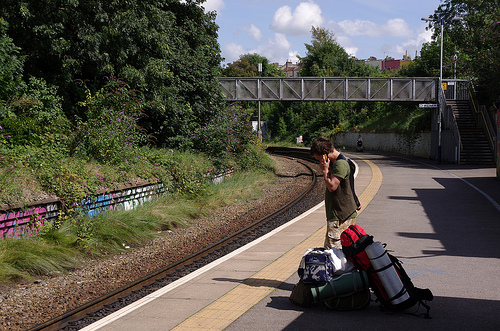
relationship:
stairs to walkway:
[429, 69, 496, 176] [420, 157, 487, 322]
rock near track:
[110, 224, 161, 266] [233, 183, 307, 244]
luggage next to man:
[331, 203, 400, 272] [278, 94, 373, 249]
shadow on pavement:
[419, 176, 463, 206] [399, 145, 477, 274]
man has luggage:
[278, 94, 373, 249] [331, 203, 400, 272]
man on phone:
[307, 137, 362, 249] [314, 149, 339, 168]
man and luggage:
[278, 94, 373, 249] [331, 203, 400, 272]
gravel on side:
[220, 193, 256, 218] [168, 174, 267, 219]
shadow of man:
[419, 176, 463, 206] [278, 94, 373, 249]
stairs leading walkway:
[429, 69, 496, 176] [420, 157, 487, 322]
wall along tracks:
[3, 176, 189, 230] [261, 140, 321, 229]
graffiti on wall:
[0, 177, 109, 237] [3, 176, 189, 230]